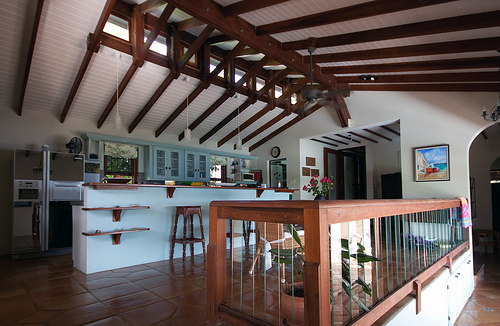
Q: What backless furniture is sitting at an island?
A: Stool.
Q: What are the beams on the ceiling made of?
A: Wood.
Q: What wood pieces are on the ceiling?
A: Beams.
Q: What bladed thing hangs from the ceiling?
A: Fan.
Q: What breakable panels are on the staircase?
A: Glass.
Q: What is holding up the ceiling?
A: Beams.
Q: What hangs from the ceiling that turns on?
A: Lights.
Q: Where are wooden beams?
A: On the ceiling.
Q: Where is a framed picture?
A: On the wall.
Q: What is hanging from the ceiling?
A: Ceiling fan.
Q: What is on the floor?
A: Brown tiles.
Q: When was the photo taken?
A: During the daytime.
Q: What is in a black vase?
A: Flowers.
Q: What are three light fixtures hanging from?
A: Ceiling.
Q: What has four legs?
A: Bar stool.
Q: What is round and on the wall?
A: Clock.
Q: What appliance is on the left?
A: Refrigerator.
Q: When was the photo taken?
A: Daytime.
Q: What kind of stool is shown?
A: Wood.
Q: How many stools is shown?
A: One.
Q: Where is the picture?
A: Wall.